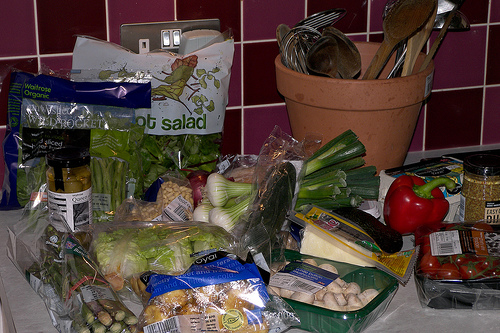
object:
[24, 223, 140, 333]
asparagus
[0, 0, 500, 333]
produce pile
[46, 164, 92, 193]
olives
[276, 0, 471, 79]
utensils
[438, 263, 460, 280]
tomato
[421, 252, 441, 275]
tomato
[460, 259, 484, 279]
tomato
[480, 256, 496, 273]
tomato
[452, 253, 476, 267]
tomato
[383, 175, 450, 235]
pepper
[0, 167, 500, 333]
counter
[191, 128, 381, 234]
leeks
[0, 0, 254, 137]
wall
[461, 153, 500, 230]
condiment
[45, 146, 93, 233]
condiment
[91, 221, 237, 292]
lettuce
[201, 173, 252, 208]
onion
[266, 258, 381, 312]
mushrooms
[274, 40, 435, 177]
container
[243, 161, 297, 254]
pickle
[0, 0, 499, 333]
produce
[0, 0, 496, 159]
pink squares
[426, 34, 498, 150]
wall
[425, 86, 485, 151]
red square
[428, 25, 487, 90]
red square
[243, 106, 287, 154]
red square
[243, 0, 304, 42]
red square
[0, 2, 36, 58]
red square